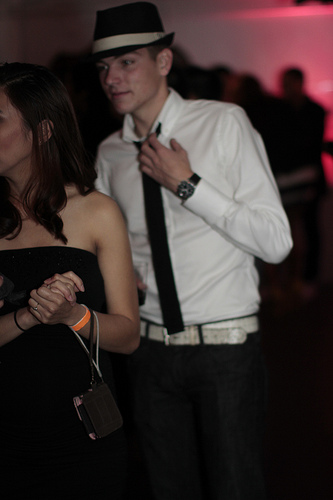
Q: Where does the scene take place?
A: At a party.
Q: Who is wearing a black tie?
A: Guy in hat.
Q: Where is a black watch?
A: Around guy's left wrist.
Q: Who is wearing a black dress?
A: Woman on left.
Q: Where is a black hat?
A: On top of guy's head.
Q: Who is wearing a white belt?
A: Guy in the hat.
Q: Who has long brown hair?
A: Woman in dress.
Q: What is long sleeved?
A: White shirt.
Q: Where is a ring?
A: Around woman's finger.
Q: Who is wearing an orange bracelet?
A: The woman.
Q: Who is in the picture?
A: A boy and girl.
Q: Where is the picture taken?
A: A dance.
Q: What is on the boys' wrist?
A: A watch.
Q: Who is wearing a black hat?
A: The boy.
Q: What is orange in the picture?
A: A wristband on the girl.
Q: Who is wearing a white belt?
A: The boy.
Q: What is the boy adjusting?
A: His tie.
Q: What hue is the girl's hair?
A: Black.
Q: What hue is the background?
A: Red.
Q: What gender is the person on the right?
A: Male.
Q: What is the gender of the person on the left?
A: Female.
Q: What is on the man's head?
A: Hat.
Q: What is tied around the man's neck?
A: Tie.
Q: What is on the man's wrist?
A: Watch.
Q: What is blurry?
A: Background.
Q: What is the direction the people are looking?
A: Left.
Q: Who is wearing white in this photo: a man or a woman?
A: A man.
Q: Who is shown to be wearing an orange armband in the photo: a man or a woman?
A: A woman.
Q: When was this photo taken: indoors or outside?
A: Indoors.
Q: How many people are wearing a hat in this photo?
A: One.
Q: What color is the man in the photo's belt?
A: White.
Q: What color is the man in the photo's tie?
A: Black.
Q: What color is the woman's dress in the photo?
A: Black.